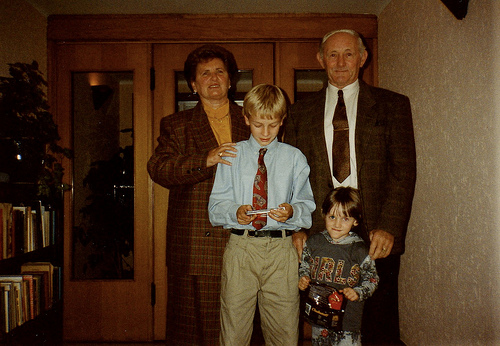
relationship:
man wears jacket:
[305, 10, 499, 271] [282, 85, 419, 257]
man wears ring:
[283, 26, 417, 346] [381, 245, 388, 251]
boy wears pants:
[208, 85, 319, 345] [214, 222, 305, 343]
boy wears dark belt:
[208, 85, 319, 345] [224, 225, 301, 239]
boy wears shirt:
[236, 85, 303, 160] [264, 159, 299, 211]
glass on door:
[54, 39, 179, 300] [55, 42, 151, 344]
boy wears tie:
[208, 85, 319, 345] [251, 148, 268, 229]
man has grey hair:
[283, 26, 417, 346] [315, 27, 384, 74]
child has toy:
[295, 182, 381, 346] [294, 275, 350, 332]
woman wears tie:
[145, 42, 254, 346] [184, 144, 212, 315]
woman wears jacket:
[145, 42, 254, 346] [146, 85, 216, 343]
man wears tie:
[283, 26, 417, 346] [305, 89, 373, 211]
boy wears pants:
[208, 85, 319, 345] [218, 227, 299, 344]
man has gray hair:
[283, 26, 417, 346] [319, 27, 364, 57]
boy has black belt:
[208, 85, 319, 345] [226, 221, 298, 238]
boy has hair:
[208, 85, 319, 345] [320, 185, 364, 224]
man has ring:
[283, 26, 417, 346] [381, 245, 388, 251]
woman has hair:
[145, 42, 254, 346] [182, 38, 241, 92]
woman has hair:
[142, 42, 247, 343] [175, 42, 244, 92]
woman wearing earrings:
[145, 42, 254, 346] [189, 81, 199, 96]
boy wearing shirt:
[208, 85, 319, 345] [213, 137, 311, 228]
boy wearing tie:
[208, 85, 319, 345] [249, 145, 272, 231]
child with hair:
[305, 182, 371, 287] [331, 191, 354, 205]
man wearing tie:
[283, 26, 417, 346] [331, 89, 351, 184]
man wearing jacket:
[283, 26, 417, 346] [302, 85, 419, 248]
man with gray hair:
[283, 26, 417, 346] [319, 27, 364, 57]